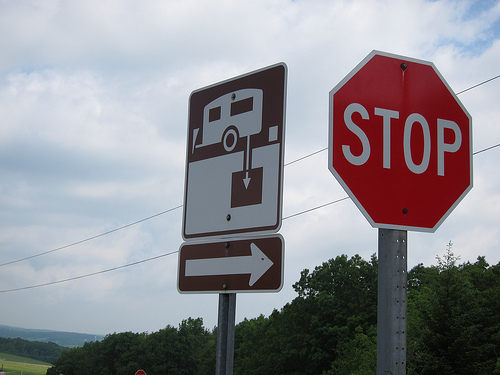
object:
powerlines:
[0, 74, 499, 266]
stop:
[341, 102, 462, 176]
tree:
[407, 255, 486, 375]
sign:
[182, 62, 287, 241]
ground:
[0, 355, 58, 374]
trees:
[293, 254, 376, 375]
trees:
[235, 316, 276, 373]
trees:
[178, 315, 207, 372]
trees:
[48, 337, 108, 375]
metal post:
[376, 227, 408, 373]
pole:
[377, 228, 407, 373]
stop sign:
[328, 48, 474, 233]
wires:
[0, 143, 500, 294]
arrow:
[242, 135, 253, 191]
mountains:
[0, 325, 105, 366]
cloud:
[1, 66, 177, 168]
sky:
[3, 2, 498, 324]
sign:
[177, 233, 285, 294]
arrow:
[184, 242, 273, 286]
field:
[2, 355, 51, 373]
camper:
[195, 88, 263, 153]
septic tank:
[231, 167, 264, 209]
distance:
[0, 123, 497, 321]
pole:
[215, 292, 237, 374]